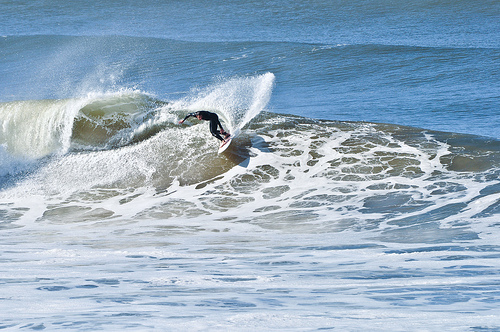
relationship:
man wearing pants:
[185, 110, 229, 146] [210, 119, 225, 143]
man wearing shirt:
[185, 110, 229, 146] [192, 110, 211, 123]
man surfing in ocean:
[185, 110, 229, 146] [7, 14, 486, 325]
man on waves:
[185, 110, 229, 146] [7, 85, 283, 184]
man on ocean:
[185, 110, 229, 146] [7, 14, 486, 325]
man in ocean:
[185, 110, 229, 146] [7, 14, 486, 325]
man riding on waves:
[185, 110, 229, 146] [7, 85, 283, 184]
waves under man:
[7, 85, 283, 184] [185, 110, 229, 146]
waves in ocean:
[7, 85, 283, 184] [7, 14, 486, 325]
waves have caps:
[7, 85, 283, 184] [35, 149, 280, 180]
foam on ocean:
[255, 143, 447, 259] [7, 14, 486, 325]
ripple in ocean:
[317, 65, 495, 105] [7, 14, 486, 325]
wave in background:
[5, 20, 488, 64] [10, 16, 496, 150]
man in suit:
[185, 110, 229, 146] [199, 112, 225, 141]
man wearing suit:
[185, 110, 229, 146] [199, 112, 225, 141]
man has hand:
[185, 110, 229, 146] [174, 111, 199, 132]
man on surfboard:
[185, 110, 229, 146] [217, 135, 238, 157]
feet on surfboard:
[218, 132, 230, 145] [217, 135, 238, 157]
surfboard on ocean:
[217, 135, 238, 157] [7, 14, 486, 325]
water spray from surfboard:
[208, 69, 277, 131] [217, 135, 238, 157]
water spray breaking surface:
[208, 69, 277, 131] [151, 60, 291, 170]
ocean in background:
[7, 14, 486, 325] [10, 16, 496, 150]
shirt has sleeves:
[192, 110, 211, 123] [186, 111, 198, 123]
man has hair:
[185, 110, 229, 146] [194, 111, 204, 117]